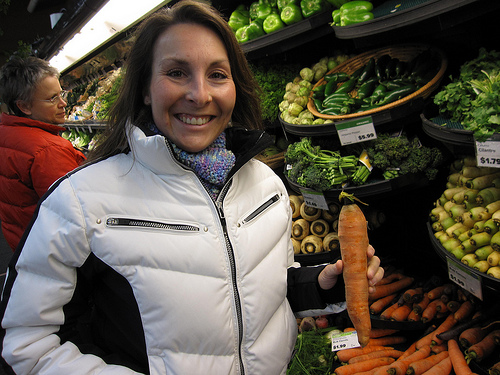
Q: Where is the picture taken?
A: A grocery.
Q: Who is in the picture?
A: A woman.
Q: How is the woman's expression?
A: She is smiling.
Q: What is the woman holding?
A: A carrot.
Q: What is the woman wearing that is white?
A: A coat.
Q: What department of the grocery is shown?
A: Produce.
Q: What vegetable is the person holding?
A: A carrot.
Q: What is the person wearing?
A: A black and white jacket.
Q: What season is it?
A: Winter.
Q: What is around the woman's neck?
A: A scarf.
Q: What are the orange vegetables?
A: Carrots.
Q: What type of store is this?
A: Grocery store.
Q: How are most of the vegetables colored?
A: Green.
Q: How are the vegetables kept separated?
A: In bins.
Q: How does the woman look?
A: Happy.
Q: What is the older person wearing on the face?
A: Glasses.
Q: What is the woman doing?
A: Smiling.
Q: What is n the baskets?
A: Vegetables.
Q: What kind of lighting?
A: Fluorescent.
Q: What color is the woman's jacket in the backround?
A: Red.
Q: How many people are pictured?
A: 2.